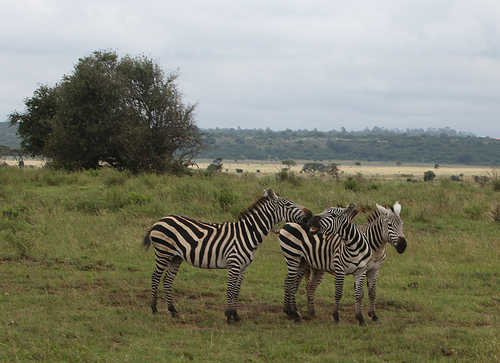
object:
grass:
[0, 160, 499, 363]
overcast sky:
[1, 0, 500, 142]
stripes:
[167, 213, 205, 240]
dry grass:
[0, 154, 499, 185]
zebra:
[138, 187, 313, 324]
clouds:
[0, 0, 499, 138]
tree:
[5, 46, 218, 177]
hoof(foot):
[148, 305, 160, 314]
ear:
[372, 199, 390, 217]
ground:
[0, 156, 499, 362]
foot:
[357, 320, 370, 328]